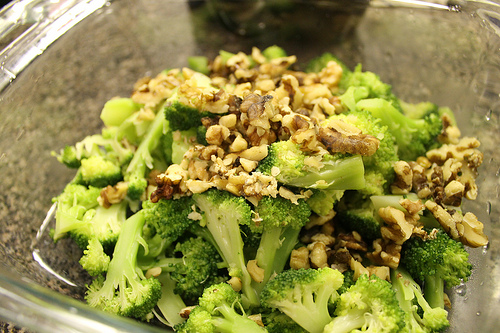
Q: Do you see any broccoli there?
A: Yes, there is broccoli.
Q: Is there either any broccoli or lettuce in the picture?
A: Yes, there is broccoli.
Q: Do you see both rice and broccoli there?
A: No, there is broccoli but no rice.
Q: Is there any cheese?
A: No, there is no cheese.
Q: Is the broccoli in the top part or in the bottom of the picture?
A: The broccoli is in the bottom of the image.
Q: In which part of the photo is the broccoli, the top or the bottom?
A: The broccoli is in the bottom of the image.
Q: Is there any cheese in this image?
A: No, there is no cheese.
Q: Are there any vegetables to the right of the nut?
A: Yes, there is a vegetable to the right of the nut.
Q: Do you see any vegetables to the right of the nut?
A: Yes, there is a vegetable to the right of the nut.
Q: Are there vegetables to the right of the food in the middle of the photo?
A: Yes, there is a vegetable to the right of the nut.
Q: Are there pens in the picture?
A: No, there are no pens.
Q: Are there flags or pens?
A: No, there are no pens or flags.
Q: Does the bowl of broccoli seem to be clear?
A: Yes, the bowl is clear.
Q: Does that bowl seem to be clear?
A: Yes, the bowl is clear.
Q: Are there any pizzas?
A: No, there are no pizzas.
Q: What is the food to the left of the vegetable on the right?
A: The food is a nut.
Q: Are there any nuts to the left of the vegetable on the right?
A: Yes, there is a nut to the left of the vegetable.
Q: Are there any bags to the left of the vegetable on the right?
A: No, there is a nut to the left of the vegetable.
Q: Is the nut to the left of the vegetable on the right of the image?
A: Yes, the nut is to the left of the vegetable.